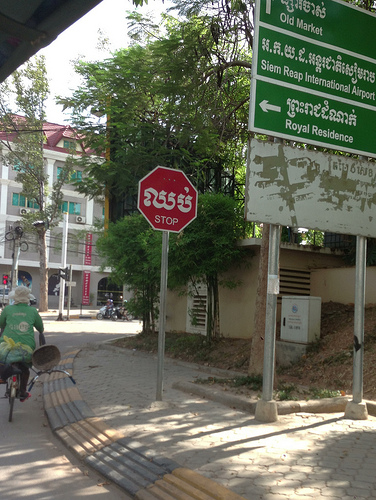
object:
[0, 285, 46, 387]
human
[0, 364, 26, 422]
bicycle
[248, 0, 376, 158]
sign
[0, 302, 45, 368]
top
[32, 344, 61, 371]
basket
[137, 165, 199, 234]
sign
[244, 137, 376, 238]
sign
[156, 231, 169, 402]
pole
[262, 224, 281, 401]
pole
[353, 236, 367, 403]
pole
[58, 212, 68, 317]
pole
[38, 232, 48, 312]
tree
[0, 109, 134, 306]
background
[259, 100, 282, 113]
directions